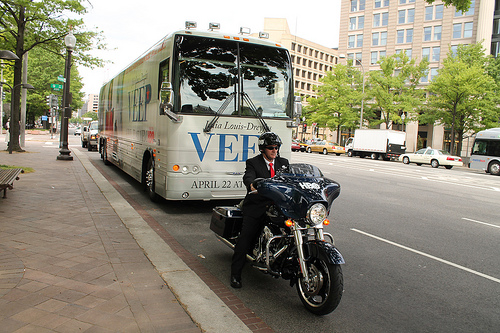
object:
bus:
[96, 17, 304, 203]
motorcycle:
[209, 161, 345, 318]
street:
[74, 123, 497, 332]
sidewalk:
[2, 130, 273, 331]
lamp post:
[57, 32, 80, 162]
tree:
[2, 1, 113, 157]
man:
[226, 132, 290, 289]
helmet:
[258, 131, 283, 152]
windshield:
[173, 35, 295, 119]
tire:
[293, 241, 348, 315]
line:
[348, 227, 500, 284]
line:
[458, 214, 500, 231]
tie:
[266, 161, 275, 178]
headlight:
[305, 203, 329, 227]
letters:
[187, 131, 261, 162]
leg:
[231, 208, 259, 289]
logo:
[296, 180, 323, 192]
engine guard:
[263, 233, 286, 273]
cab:
[396, 146, 463, 170]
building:
[335, 1, 497, 163]